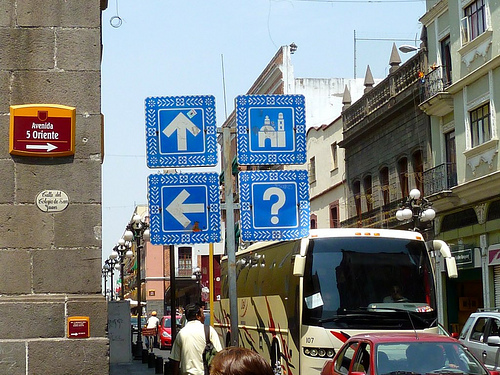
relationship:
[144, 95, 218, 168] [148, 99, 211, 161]
blue sign pointing arrow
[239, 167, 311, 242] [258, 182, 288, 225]
blue sign with question mark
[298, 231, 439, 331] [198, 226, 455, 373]
window of a bus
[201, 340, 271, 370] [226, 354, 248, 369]
person has hair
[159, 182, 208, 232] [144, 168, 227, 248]
arrow on sign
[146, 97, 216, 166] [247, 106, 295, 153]
blue sign has building pic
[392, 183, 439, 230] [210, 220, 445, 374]
lamp near bus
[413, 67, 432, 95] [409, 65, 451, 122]
person on balcony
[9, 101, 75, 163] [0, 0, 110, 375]
sign on wall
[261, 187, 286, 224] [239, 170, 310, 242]
question mark on blue sign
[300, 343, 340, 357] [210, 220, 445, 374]
headlight on bus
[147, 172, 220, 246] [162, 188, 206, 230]
blue sign has arrow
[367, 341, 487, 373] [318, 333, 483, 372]
windshield of a car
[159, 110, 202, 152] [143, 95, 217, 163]
arrow on sign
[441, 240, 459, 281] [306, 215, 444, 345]
view mirror of bus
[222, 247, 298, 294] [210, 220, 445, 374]
windows of bus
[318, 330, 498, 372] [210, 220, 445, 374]
car by bus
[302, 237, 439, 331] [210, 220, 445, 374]
window of bus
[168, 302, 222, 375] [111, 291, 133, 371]
man walking down street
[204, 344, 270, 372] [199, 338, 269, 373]
hair of person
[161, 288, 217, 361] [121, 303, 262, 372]
man walking down street